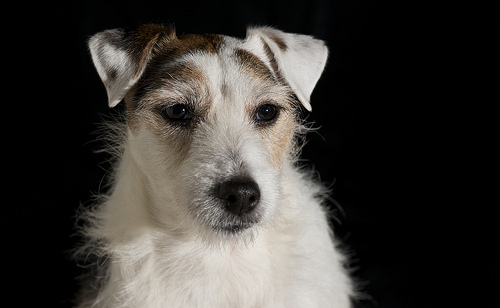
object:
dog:
[76, 26, 356, 308]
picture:
[6, 6, 493, 306]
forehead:
[151, 54, 275, 90]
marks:
[148, 59, 197, 88]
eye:
[159, 102, 195, 123]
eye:
[254, 102, 280, 122]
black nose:
[218, 175, 260, 215]